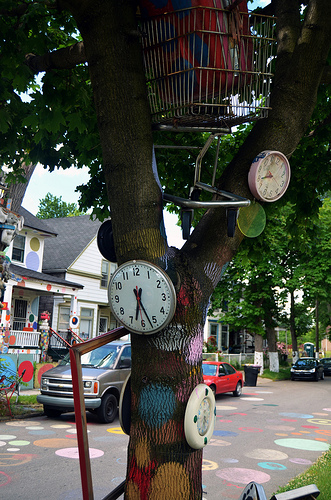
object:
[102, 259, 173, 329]
clock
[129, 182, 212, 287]
tree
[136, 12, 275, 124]
basket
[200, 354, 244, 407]
car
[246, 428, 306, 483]
circles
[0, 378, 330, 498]
street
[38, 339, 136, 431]
van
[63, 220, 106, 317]
house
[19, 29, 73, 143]
trees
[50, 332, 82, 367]
steps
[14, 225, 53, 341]
house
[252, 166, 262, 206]
metal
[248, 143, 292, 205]
clock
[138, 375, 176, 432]
circle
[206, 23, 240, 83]
red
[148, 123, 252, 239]
cart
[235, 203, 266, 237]
circle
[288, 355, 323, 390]
car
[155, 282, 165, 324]
numbers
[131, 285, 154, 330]
hands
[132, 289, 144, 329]
hand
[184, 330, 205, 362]
circle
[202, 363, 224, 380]
windshield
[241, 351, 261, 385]
can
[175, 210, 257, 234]
wheels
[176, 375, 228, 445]
clock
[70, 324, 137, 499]
frame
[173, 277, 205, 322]
circle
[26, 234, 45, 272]
circles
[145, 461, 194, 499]
circle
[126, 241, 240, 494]
circles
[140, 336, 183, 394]
trunk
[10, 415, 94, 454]
paint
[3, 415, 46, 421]
curb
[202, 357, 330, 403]
cars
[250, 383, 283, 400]
road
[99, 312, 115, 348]
screendoor